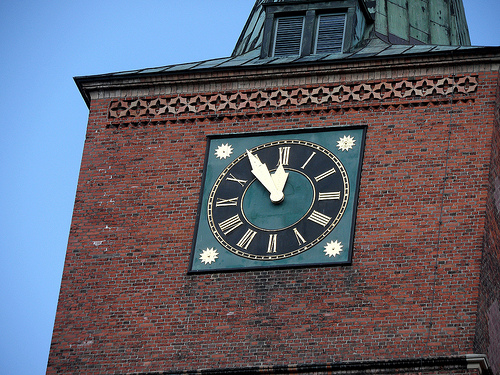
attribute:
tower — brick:
[37, 11, 498, 367]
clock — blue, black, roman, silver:
[203, 140, 353, 268]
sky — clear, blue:
[3, 6, 229, 164]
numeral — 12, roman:
[276, 142, 291, 170]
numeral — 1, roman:
[295, 147, 322, 170]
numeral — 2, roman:
[310, 160, 341, 186]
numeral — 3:
[316, 192, 342, 203]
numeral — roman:
[311, 207, 331, 230]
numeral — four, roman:
[312, 213, 330, 227]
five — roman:
[289, 231, 306, 245]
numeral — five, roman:
[289, 225, 309, 248]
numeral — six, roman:
[269, 229, 278, 257]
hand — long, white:
[240, 151, 273, 187]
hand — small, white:
[274, 165, 288, 185]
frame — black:
[190, 130, 357, 275]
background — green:
[189, 138, 365, 274]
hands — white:
[246, 148, 292, 203]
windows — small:
[257, 11, 350, 56]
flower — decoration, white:
[214, 145, 234, 159]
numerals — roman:
[214, 147, 340, 260]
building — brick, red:
[56, 87, 495, 359]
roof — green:
[83, 45, 500, 76]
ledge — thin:
[69, 58, 483, 79]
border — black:
[178, 126, 388, 277]